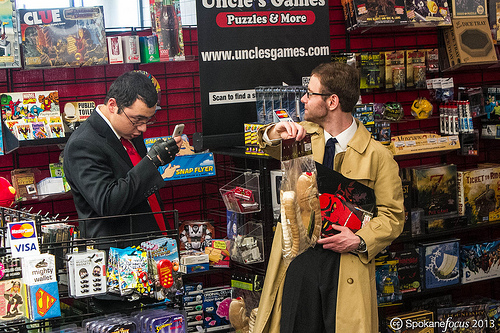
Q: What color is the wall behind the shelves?
A: Red.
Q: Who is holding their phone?
A: Man.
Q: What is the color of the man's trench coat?
A: Tan.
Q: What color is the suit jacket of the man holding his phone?
A: Black.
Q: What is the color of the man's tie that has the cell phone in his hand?
A: Red.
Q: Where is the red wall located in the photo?
A: Behind the shelves.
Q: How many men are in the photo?
A: Two.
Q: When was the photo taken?
A: Daytime.